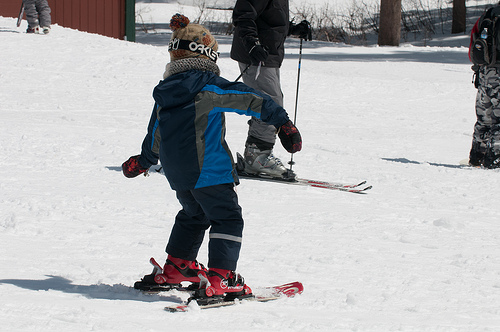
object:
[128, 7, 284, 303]
kid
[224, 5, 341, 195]
person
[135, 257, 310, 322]
skis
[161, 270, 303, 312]
skis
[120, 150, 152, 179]
mitten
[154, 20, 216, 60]
hat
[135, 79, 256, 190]
jacket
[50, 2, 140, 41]
building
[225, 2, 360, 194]
person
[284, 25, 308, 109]
ski poles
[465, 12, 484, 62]
backpack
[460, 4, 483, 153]
person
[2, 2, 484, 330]
snow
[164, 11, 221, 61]
beanie hat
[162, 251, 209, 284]
ski boot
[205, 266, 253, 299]
ski boot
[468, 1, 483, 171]
person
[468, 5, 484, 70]
backpack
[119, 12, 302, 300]
child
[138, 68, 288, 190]
jacket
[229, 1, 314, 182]
man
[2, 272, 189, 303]
shadow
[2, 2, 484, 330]
ground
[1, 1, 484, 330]
ski resort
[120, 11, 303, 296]
kid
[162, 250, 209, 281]
ski shoe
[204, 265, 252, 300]
ski shoe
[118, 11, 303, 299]
person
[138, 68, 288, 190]
coat